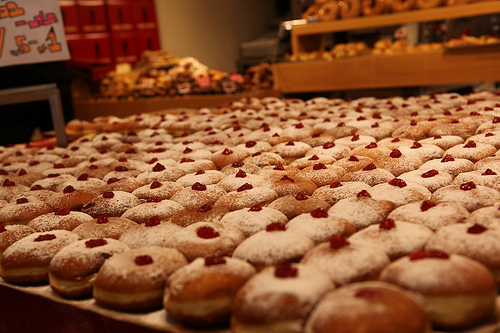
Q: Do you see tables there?
A: Yes, there is a table.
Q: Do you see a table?
A: Yes, there is a table.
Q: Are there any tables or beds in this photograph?
A: Yes, there is a table.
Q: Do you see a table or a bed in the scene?
A: Yes, there is a table.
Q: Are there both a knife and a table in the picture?
A: No, there is a table but no knives.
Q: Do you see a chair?
A: No, there are no chairs.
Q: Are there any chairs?
A: No, there are no chairs.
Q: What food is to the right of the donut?
A: The food is pastries.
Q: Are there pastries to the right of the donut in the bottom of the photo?
A: Yes, there are pastries to the right of the doughnut.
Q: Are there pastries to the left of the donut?
A: No, the pastries are to the right of the donut.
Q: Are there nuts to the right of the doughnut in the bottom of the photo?
A: No, there are pastries to the right of the donut.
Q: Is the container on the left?
A: Yes, the container is on the left of the image.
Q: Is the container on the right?
A: No, the container is on the left of the image.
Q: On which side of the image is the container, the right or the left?
A: The container is on the left of the image.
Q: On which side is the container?
A: The container is on the left of the image.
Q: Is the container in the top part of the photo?
A: Yes, the container is in the top of the image.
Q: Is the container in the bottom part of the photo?
A: No, the container is in the top of the image.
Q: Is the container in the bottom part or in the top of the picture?
A: The container is in the top of the image.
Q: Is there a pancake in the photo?
A: No, there are no pancakes.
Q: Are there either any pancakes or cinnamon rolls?
A: No, there are no pancakes or cinnamon rolls.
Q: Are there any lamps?
A: No, there are no lamps.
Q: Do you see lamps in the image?
A: No, there are no lamps.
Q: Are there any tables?
A: Yes, there is a table.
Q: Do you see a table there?
A: Yes, there is a table.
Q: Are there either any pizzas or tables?
A: Yes, there is a table.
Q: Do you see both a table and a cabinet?
A: No, there is a table but no cabinets.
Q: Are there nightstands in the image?
A: No, there are no nightstands.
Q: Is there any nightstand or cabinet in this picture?
A: No, there are no nightstands or cabinets.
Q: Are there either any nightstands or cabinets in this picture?
A: No, there are no nightstands or cabinets.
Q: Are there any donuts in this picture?
A: Yes, there is a donut.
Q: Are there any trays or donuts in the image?
A: Yes, there is a donut.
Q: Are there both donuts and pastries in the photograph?
A: Yes, there are both a donut and a pastry.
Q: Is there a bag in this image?
A: No, there are no bags.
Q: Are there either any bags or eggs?
A: No, there are no bags or eggs.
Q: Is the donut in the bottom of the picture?
A: Yes, the donut is in the bottom of the image.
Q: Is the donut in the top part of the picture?
A: No, the donut is in the bottom of the image.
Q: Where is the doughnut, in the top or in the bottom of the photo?
A: The doughnut is in the bottom of the image.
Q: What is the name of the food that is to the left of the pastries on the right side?
A: The food is a donut.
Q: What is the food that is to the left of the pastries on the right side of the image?
A: The food is a donut.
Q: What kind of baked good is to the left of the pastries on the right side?
A: The food is a donut.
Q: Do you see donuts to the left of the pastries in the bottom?
A: Yes, there is a donut to the left of the pastries.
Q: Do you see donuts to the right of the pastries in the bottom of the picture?
A: No, the donut is to the left of the pastries.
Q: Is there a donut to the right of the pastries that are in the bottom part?
A: No, the donut is to the left of the pastries.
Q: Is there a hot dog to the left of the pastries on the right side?
A: No, there is a donut to the left of the pastries.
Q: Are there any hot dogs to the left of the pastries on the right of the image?
A: No, there is a donut to the left of the pastries.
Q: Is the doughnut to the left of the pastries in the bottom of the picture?
A: Yes, the doughnut is to the left of the pastries.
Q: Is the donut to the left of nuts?
A: No, the donut is to the left of the pastries.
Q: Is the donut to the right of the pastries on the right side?
A: No, the donut is to the left of the pastries.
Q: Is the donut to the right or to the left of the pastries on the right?
A: The donut is to the left of the pastries.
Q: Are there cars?
A: No, there are no cars.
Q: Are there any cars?
A: No, there are no cars.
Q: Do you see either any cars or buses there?
A: No, there are no cars or buses.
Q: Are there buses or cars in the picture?
A: No, there are no cars or buses.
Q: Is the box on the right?
A: No, the box is on the left of the image.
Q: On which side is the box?
A: The box is on the left of the image.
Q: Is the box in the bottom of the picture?
A: No, the box is in the top of the image.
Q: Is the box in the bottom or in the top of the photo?
A: The box is in the top of the image.